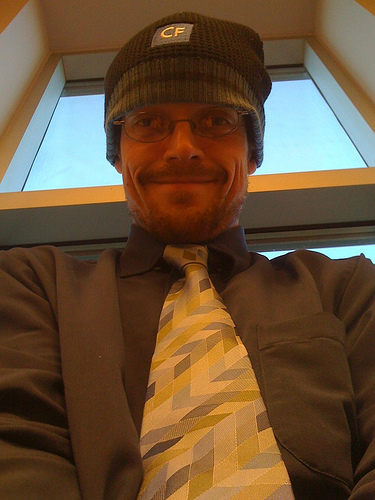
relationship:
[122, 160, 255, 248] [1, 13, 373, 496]
facial hair on man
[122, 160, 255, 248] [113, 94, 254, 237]
facial hair on face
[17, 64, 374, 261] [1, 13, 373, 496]
window behind man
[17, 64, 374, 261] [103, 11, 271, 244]
window behind head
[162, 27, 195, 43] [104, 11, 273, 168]
cf written on beanie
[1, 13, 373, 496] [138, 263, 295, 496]
man wearing tie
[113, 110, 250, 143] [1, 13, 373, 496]
eye glasses on man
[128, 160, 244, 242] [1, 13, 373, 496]
facial hair on man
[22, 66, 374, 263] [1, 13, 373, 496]
window behind man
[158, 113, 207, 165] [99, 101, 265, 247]
nose on face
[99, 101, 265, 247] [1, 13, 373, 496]
face on man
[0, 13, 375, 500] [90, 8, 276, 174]
man wearing beanie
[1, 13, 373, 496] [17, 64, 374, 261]
man in front of window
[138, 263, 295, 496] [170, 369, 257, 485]
tie has design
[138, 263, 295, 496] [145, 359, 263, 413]
tie has design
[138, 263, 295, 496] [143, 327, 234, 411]
tie has design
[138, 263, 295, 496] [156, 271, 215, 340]
tie has design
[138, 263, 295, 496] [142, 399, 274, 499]
tie has design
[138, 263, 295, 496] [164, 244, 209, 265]
tie has design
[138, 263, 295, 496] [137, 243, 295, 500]
tie has design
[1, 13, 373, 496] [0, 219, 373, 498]
man has shirt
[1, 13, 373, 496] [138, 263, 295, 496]
man has tie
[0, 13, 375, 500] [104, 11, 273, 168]
man has beanie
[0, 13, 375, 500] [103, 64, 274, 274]
man has head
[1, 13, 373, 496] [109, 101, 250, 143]
man has eye glasses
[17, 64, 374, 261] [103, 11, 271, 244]
window above head